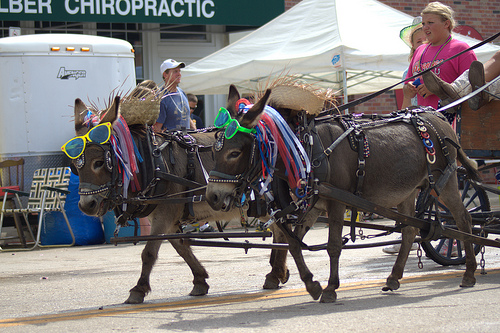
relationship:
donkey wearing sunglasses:
[129, 79, 161, 100] [208, 103, 255, 141]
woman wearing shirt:
[400, 1, 481, 139] [402, 42, 479, 132]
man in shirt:
[149, 54, 198, 139] [156, 84, 195, 130]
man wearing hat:
[149, 54, 198, 139] [156, 55, 185, 79]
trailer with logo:
[0, 28, 139, 165] [52, 63, 90, 84]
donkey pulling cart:
[129, 79, 161, 100] [415, 89, 498, 269]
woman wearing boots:
[402, 0, 476, 129] [419, 53, 476, 120]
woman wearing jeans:
[402, 0, 476, 129] [443, 100, 484, 195]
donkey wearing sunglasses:
[37, 99, 173, 251] [45, 119, 125, 161]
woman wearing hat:
[386, 10, 429, 58] [399, 18, 420, 37]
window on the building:
[121, 26, 132, 44] [66, 8, 185, 30]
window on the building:
[112, 17, 131, 37] [112, 4, 202, 37]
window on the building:
[108, 28, 140, 38] [114, 0, 214, 43]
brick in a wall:
[385, 93, 392, 103] [458, 97, 484, 137]